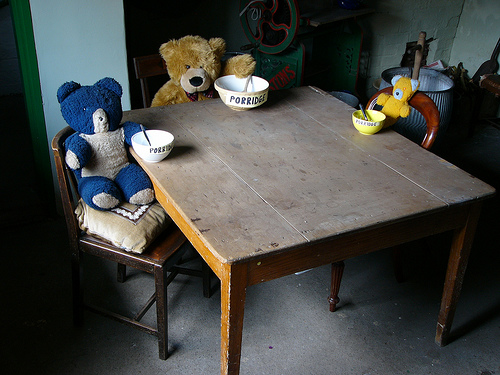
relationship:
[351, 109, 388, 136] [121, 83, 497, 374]
bowl sitting on dining table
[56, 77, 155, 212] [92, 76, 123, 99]
bear has ear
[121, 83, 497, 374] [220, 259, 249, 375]
dining table has leg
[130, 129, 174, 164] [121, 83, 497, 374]
bowl sitting on dining table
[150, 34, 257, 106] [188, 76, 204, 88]
teddy bear has nose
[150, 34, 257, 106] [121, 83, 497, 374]
teddy bear around dining table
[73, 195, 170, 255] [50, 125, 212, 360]
throw pillow on top of chair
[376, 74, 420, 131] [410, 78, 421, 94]
teddy bear has ear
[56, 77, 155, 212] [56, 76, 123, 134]
bear has head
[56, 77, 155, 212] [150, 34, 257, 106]
bear next to teddy bear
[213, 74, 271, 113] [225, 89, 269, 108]
bowl with label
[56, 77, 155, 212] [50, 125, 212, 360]
bear sitting on chair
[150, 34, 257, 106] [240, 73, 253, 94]
teddy bear holding spoon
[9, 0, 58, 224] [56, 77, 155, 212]
door frame behind bear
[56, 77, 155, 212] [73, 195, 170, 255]
bear sitting on throw pillow